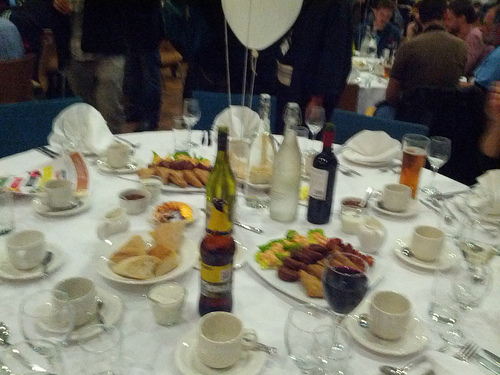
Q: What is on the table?
A: Food.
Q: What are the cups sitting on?
A: Saucers.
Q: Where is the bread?
A: In the white plate.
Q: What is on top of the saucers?
A: Cups.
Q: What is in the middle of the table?
A: Five bottles.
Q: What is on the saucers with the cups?
A: Spoons.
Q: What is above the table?
A: A balloon.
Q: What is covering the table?
A: A white tablecloth.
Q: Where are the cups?
A: On the table.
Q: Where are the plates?
A: On the table.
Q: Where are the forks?
A: On the table.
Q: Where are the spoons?
A: On the table.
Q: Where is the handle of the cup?
A: On the cup.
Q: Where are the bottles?
A: On the table.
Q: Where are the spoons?
A: On the table.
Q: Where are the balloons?
A: On the table.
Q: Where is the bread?
A: On the table.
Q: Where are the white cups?
A: On saucers.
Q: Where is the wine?
A: Center of the table.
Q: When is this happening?
A: A celebration.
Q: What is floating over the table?
A: Balloon.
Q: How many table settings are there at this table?
A: 10.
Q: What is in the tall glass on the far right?
A: Beer.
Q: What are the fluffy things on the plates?
A: Napkins.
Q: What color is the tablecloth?
A: White.